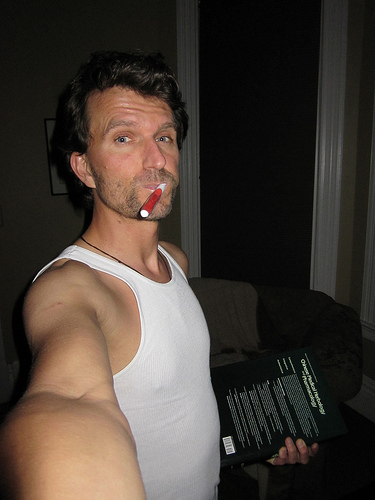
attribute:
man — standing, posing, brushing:
[5, 47, 221, 498]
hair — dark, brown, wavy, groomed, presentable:
[50, 48, 187, 214]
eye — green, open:
[111, 132, 135, 144]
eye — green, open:
[155, 134, 178, 144]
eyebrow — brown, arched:
[100, 119, 136, 136]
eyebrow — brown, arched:
[154, 119, 179, 133]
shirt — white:
[34, 246, 226, 499]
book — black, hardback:
[210, 342, 352, 467]